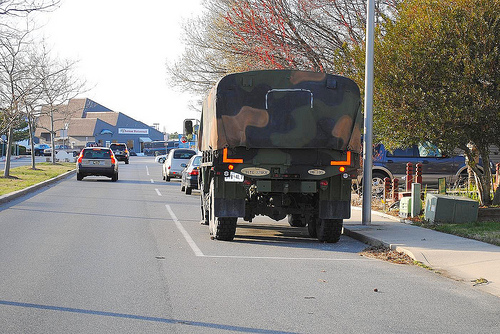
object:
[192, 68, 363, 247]
truck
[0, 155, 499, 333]
road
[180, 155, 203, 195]
car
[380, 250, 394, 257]
leaves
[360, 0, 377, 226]
pole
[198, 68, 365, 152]
camoflauged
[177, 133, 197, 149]
sign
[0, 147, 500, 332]
street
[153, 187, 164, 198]
line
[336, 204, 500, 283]
sidewalk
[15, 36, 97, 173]
trees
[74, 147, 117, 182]
cars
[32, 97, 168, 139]
roof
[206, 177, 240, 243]
tires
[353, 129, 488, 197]
suv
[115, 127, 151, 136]
sign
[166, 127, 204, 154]
post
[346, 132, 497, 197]
driveway